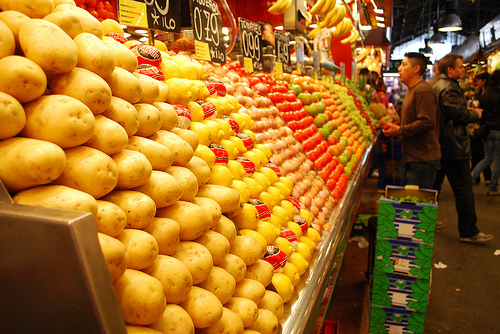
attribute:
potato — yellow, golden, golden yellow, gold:
[88, 149, 215, 308]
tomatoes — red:
[276, 100, 330, 160]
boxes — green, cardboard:
[374, 220, 442, 333]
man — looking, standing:
[375, 53, 440, 174]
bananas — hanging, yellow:
[305, 3, 359, 46]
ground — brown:
[442, 233, 499, 321]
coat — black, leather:
[442, 82, 468, 144]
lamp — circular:
[437, 10, 461, 42]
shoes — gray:
[459, 228, 500, 248]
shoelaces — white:
[479, 230, 486, 238]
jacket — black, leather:
[439, 84, 467, 150]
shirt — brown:
[401, 97, 437, 156]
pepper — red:
[383, 121, 406, 132]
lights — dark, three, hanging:
[396, 35, 469, 62]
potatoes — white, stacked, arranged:
[126, 190, 231, 304]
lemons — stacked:
[215, 143, 275, 203]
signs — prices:
[188, 13, 321, 78]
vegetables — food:
[168, 72, 373, 189]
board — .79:
[183, 9, 234, 76]